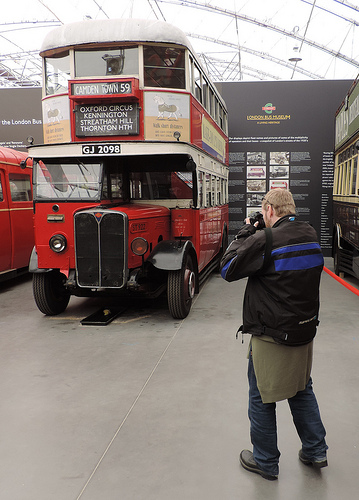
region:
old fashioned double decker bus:
[37, 17, 232, 326]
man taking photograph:
[232, 180, 342, 483]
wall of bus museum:
[231, 83, 330, 183]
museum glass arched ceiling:
[5, 4, 357, 73]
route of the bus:
[65, 76, 143, 138]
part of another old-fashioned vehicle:
[1, 146, 34, 299]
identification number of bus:
[76, 138, 126, 158]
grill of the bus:
[71, 202, 132, 297]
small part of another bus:
[327, 81, 356, 287]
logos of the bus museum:
[0, 98, 306, 127]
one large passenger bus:
[21, 11, 226, 318]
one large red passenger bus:
[17, 11, 228, 346]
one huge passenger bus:
[18, 9, 231, 347]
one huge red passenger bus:
[18, 16, 228, 352]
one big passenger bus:
[26, 12, 226, 353]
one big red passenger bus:
[20, 14, 229, 380]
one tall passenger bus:
[21, 13, 227, 351]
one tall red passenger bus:
[24, 10, 224, 345]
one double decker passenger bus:
[16, 8, 226, 327]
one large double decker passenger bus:
[26, 6, 225, 339]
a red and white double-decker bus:
[23, 13, 239, 326]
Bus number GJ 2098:
[68, 138, 135, 165]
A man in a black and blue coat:
[211, 174, 341, 483]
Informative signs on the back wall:
[231, 147, 317, 233]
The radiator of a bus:
[62, 197, 140, 302]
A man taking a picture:
[214, 184, 330, 309]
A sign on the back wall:
[238, 94, 306, 131]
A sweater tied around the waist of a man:
[222, 306, 330, 410]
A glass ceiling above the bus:
[2, 1, 357, 97]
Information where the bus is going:
[63, 71, 148, 145]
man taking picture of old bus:
[216, 184, 338, 479]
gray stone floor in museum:
[2, 207, 357, 498]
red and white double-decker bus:
[21, 6, 235, 323]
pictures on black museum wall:
[240, 141, 294, 264]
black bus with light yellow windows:
[328, 71, 357, 289]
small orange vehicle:
[0, 139, 50, 300]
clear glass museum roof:
[0, 0, 358, 92]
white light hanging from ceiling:
[284, 22, 308, 67]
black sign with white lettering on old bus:
[66, 74, 144, 141]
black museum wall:
[0, 76, 357, 262]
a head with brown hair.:
[257, 186, 298, 232]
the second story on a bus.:
[34, 19, 232, 168]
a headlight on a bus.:
[42, 227, 73, 261]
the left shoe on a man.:
[232, 446, 283, 482]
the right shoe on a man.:
[291, 441, 338, 473]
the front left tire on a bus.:
[159, 238, 204, 322]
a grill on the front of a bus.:
[69, 205, 133, 296]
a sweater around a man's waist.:
[243, 332, 316, 423]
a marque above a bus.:
[65, 65, 147, 142]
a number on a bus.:
[74, 130, 129, 161]